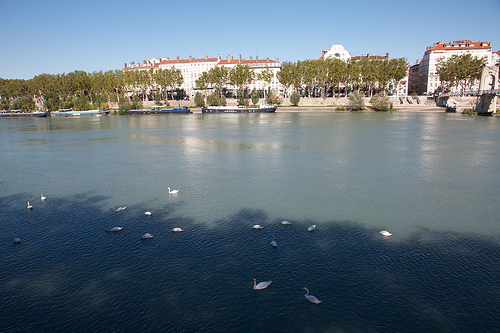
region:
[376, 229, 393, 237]
white bird in water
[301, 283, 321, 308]
white bird in water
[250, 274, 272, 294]
white bird in water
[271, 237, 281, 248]
white bird in water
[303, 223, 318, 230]
white bird in water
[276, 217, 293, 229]
white bird in water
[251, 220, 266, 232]
white bird in water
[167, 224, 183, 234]
white bird in water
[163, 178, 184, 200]
white bird in water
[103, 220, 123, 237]
white bird in water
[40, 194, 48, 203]
white bird in water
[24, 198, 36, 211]
white bird in water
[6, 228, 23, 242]
white bird in water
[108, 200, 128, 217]
white bird in water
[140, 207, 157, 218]
white bird in water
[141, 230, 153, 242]
white bird in water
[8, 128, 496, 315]
water in front of buildings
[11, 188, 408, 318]
birds in the water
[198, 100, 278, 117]
boat in the water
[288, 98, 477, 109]
concrete by the water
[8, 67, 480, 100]
trees in front of buildings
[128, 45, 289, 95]
building across from water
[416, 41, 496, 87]
building across from water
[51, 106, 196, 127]
boats in front of building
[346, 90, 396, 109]
bushes near the water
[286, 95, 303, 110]
bush in front of building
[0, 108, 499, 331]
the body of water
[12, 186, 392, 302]
the group of birds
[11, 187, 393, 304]
the birds on the water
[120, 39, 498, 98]
the buildings across the water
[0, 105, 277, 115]
the boats on the water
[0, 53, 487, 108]
the trees in front of the buildings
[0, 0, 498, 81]
the blue sky above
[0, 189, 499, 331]
the shadow on the water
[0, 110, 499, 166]
the reflection on the water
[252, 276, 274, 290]
the bird on the water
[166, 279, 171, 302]
part of the ocean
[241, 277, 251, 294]
part of a shadow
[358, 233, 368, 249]
edge of a shadow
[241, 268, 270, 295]
The swan in the water is white.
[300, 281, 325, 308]
The swan in the blue water has a long neck.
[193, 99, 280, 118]
There is a long boat that is blue and white in the water.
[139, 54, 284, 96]
white building with red roof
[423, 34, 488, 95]
white building with red roof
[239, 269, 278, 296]
white swan in blue canal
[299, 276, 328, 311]
white swan in blue canal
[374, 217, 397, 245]
white swan in blue canal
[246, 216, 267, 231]
white swan in blue canal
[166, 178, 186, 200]
white swan in blue canal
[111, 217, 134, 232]
white swan in blue canal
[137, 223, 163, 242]
white swan in blue canal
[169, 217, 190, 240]
white swan in blue canal